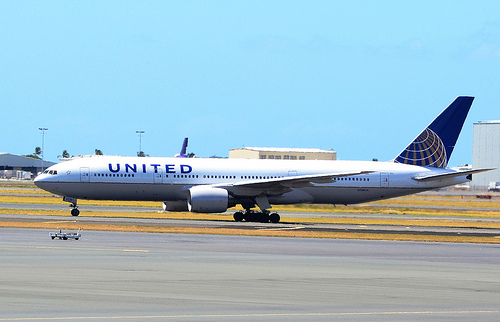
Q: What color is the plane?
A: Silver.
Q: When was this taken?
A: During the day.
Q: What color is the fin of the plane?
A: Blue.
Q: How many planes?
A: One.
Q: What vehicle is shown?
A: A plane.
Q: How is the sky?
A: Clear.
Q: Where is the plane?
A: On runway.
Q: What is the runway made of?
A: Asphalt.